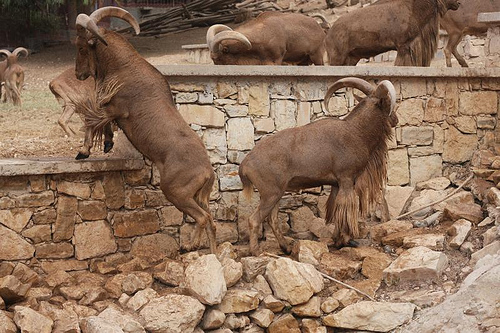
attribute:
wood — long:
[408, 175, 474, 217]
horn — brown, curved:
[325, 66, 369, 108]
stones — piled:
[35, 250, 310, 325]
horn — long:
[205, 22, 255, 53]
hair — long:
[324, 115, 393, 239]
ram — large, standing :
[322, 2, 453, 72]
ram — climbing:
[64, 20, 225, 220]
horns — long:
[317, 59, 404, 121]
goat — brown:
[74, 6, 219, 261]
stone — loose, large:
[320, 295, 423, 332]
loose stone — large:
[256, 253, 331, 305]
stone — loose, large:
[321, 300, 419, 332]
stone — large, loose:
[181, 252, 227, 304]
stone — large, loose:
[263, 255, 324, 303]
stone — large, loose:
[81, 305, 146, 331]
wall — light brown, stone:
[423, 114, 474, 164]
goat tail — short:
[219, 169, 267, 203]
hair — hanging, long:
[322, 121, 394, 236]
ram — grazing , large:
[202, 8, 327, 63]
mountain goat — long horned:
[65, 5, 222, 265]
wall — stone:
[0, 61, 499, 265]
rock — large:
[321, 300, 413, 331]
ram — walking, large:
[248, 84, 400, 248]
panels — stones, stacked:
[101, 0, 335, 62]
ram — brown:
[236, 78, 408, 248]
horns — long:
[72, 0, 152, 43]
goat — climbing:
[41, 0, 236, 266]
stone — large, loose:
[10, 219, 497, 328]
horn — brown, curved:
[374, 80, 404, 118]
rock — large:
[132, 286, 206, 331]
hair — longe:
[339, 176, 388, 236]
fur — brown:
[106, 45, 173, 135]